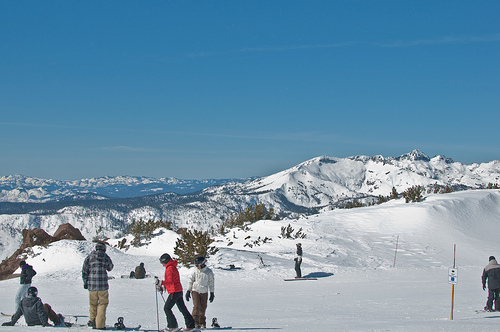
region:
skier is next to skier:
[152, 249, 198, 329]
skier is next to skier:
[186, 253, 217, 330]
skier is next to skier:
[80, 240, 114, 329]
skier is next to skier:
[1, 284, 78, 328]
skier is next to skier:
[15, 255, 40, 312]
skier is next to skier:
[482, 256, 499, 314]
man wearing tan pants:
[80, 242, 112, 329]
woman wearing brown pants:
[187, 256, 219, 326]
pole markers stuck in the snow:
[393, 238, 463, 315]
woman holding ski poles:
[149, 254, 189, 326]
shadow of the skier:
[301, 268, 329, 280]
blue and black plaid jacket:
[79, 242, 115, 287]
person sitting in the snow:
[8, 291, 63, 325]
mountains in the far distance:
[5, 168, 202, 204]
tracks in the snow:
[353, 220, 433, 275]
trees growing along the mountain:
[108, 184, 425, 259]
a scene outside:
[0, 5, 498, 329]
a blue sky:
[0, 2, 499, 210]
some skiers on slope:
[6, 198, 268, 330]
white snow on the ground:
[10, 171, 497, 331]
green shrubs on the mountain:
[193, 186, 311, 256]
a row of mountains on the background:
[0, 146, 499, 310]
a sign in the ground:
[435, 232, 476, 329]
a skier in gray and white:
[473, 242, 498, 330]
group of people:
[2, 192, 494, 330]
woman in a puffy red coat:
[152, 249, 193, 330]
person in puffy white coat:
[187, 253, 217, 326]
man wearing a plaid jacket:
[81, 240, 114, 328]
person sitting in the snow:
[1, 283, 73, 330]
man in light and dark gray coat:
[477, 253, 498, 309]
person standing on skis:
[285, 238, 318, 284]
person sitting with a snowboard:
[121, 260, 151, 281]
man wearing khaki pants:
[80, 238, 115, 330]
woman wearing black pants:
[154, 251, 194, 329]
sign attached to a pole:
[446, 240, 459, 320]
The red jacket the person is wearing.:
[163, 261, 179, 293]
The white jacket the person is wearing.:
[190, 267, 213, 294]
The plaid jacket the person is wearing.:
[83, 249, 110, 289]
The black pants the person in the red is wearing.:
[162, 289, 192, 330]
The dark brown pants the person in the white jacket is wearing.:
[191, 287, 206, 325]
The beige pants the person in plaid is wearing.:
[86, 292, 110, 326]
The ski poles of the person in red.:
[151, 278, 172, 330]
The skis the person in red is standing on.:
[142, 325, 204, 330]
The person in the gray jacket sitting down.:
[9, 279, 77, 329]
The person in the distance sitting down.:
[126, 262, 150, 279]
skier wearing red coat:
[151, 249, 198, 329]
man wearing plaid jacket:
[80, 240, 114, 326]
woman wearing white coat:
[180, 259, 218, 321]